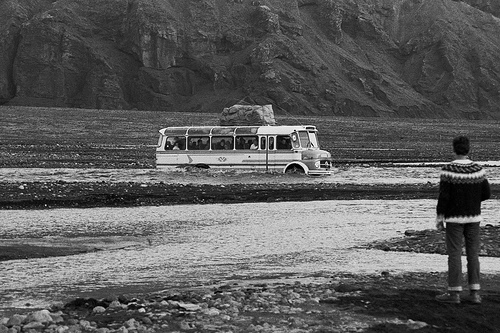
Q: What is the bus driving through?
A: The water.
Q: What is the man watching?
A: The bus.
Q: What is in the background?
A: The hill.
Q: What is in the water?
A: The bus.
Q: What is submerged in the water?
A: The bus.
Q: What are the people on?
A: The bus.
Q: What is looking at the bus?
A: The guy.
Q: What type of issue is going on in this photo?
A: Flooding.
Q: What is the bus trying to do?
A: Forage the flood.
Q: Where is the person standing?
A: Bottom right corner of the photo.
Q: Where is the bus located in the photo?
A: Center.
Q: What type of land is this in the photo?
A: Canyon.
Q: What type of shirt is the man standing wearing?
A: Hand made sweater.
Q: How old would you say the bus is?
A: Really old.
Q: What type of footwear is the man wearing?
A: Tennis shoes.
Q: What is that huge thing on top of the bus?
A: Luggage.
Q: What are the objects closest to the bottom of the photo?
A: Rocks and pebbles.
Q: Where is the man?
A: On the shore.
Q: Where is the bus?
A: In the water.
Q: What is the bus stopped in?
A: Water.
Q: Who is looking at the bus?
A: A person in a sweater.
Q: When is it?
A: Daytime.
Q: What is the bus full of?
A: People.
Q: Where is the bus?
A: In the water.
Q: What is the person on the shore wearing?
A: A sweater.